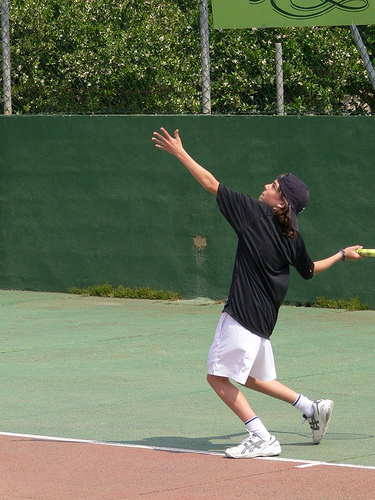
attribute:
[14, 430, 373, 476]
line — white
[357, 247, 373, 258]
grip — neon, green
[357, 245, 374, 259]
handle — neon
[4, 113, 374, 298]
wall — dark green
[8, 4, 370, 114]
bushes — green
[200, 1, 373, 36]
sign — black, yellow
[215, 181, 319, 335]
shirt — black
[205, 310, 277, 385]
shorts — white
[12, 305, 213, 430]
court — red, green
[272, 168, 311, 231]
hat — black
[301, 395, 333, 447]
shoe — black, white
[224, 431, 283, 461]
shoe — black, white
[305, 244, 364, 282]
right arm — lower